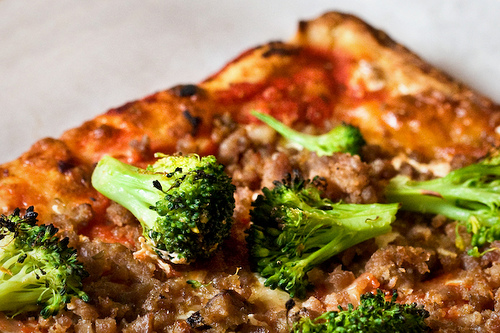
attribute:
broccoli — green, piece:
[92, 153, 239, 261]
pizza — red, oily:
[1, 11, 500, 332]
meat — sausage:
[220, 127, 383, 212]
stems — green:
[91, 153, 158, 207]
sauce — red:
[247, 46, 366, 131]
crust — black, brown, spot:
[304, 1, 499, 130]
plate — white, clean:
[1, 2, 500, 160]